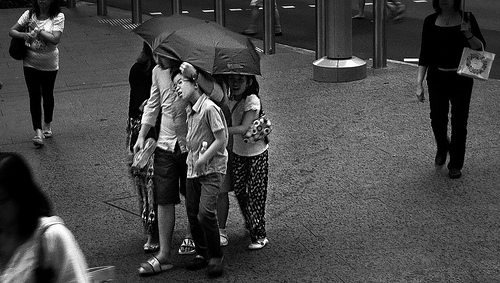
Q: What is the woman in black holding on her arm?
A: Bag.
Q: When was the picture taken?
A: Daytime.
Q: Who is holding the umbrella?
A: A man.